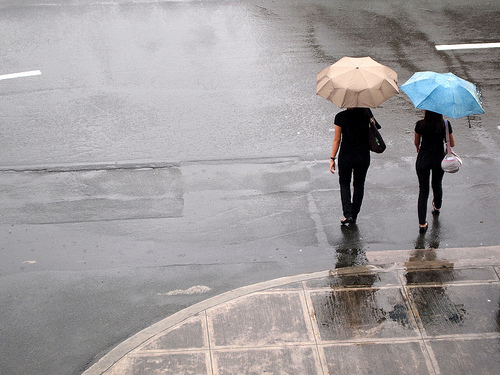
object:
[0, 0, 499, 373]
environment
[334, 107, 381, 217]
clothes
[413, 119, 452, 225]
clothes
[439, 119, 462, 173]
purse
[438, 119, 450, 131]
shoulder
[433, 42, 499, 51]
line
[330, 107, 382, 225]
pedestrians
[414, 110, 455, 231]
pedestrian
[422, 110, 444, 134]
hair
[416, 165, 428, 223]
leg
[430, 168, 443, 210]
leg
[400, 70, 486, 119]
umbrella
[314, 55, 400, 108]
umbrella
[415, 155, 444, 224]
pants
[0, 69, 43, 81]
lines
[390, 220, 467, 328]
reflection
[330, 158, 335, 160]
watch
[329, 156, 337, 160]
wristwatch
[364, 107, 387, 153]
purse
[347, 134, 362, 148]
black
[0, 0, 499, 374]
street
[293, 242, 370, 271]
puddle